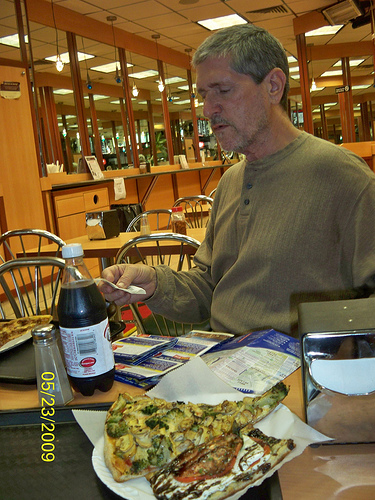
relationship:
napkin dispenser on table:
[296, 297, 375, 444] [2, 331, 373, 499]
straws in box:
[45, 159, 66, 173] [48, 170, 69, 187]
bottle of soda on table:
[55, 240, 118, 397] [2, 331, 373, 499]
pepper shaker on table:
[30, 321, 76, 409] [2, 331, 373, 499]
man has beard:
[99, 21, 374, 333] [209, 106, 275, 154]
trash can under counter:
[113, 200, 146, 232] [49, 157, 231, 206]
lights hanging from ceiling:
[46, 5, 196, 106] [3, 3, 374, 98]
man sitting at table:
[99, 21, 374, 333] [2, 331, 373, 499]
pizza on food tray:
[154, 432, 296, 499] [1, 401, 283, 498]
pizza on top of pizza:
[154, 432, 296, 499] [154, 432, 296, 499]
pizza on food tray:
[0, 314, 53, 349] [0, 319, 125, 389]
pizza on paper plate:
[0, 314, 53, 349] [2, 324, 53, 352]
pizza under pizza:
[154, 432, 296, 499] [154, 432, 296, 499]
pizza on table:
[154, 432, 296, 499] [2, 331, 373, 499]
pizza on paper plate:
[154, 432, 296, 499] [2, 324, 53, 352]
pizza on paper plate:
[154, 432, 296, 499] [88, 393, 294, 499]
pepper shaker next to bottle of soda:
[30, 321, 76, 409] [55, 240, 118, 397]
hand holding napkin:
[101, 262, 157, 308] [92, 275, 147, 300]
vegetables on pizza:
[140, 403, 186, 435] [154, 432, 296, 499]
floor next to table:
[3, 275, 67, 320] [18, 227, 206, 261]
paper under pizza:
[72, 354, 332, 499] [154, 432, 296, 499]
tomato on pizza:
[177, 440, 241, 482] [154, 432, 296, 499]